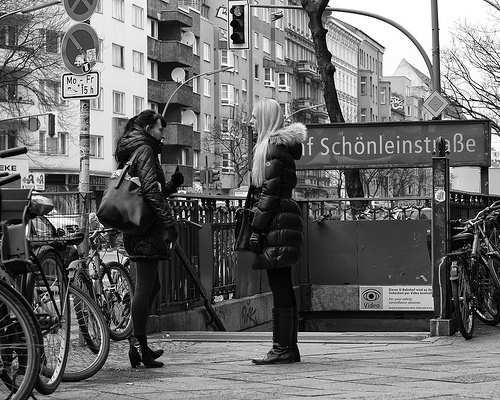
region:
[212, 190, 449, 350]
Entrance to underground subway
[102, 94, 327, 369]
Two women talking on street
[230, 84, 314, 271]
Woman with blond hair and black jacket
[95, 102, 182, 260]
Woman with dark hair and dark jacket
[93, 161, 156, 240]
Purse on woman's shoulder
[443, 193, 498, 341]
Bicycle up against wall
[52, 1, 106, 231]
Street sign in city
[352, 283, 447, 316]
Video recording warning sign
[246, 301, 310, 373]
Black boots woman is wearing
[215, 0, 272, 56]
Traffic signal over street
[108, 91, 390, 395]
two women are talking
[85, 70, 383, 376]
two women standing at the subway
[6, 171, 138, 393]
the bikes are parked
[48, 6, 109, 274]
signs on the pole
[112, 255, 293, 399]
women are wearing boots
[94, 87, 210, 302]
a woman is carrying a shoulder bag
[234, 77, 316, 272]
the woman is blonde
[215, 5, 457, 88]
traffic light attached to a pole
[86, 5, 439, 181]
the buildings beside the street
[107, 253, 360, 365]
the women are wearing leggings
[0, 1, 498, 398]
picture was taken in berlin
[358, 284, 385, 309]
video [eye] warning on subway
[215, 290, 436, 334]
entrance to subway w/ graffiti on left concrete wall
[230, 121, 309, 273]
a puffy jacket w/ a furry hood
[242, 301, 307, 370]
flat mid calf boots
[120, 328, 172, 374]
medium heel ankle boots, dark colour, metallic stripe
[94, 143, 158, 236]
overfull one shoulder tote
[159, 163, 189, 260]
black or dark colour pair of gloves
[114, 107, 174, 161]
a large hood on a jacket worn by a dark haired woman w/ a ponytail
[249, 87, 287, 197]
long straight blonde hair any woman in the late 60s wouldve killed for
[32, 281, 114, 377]
the rubber wheel of the bike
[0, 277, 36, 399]
the rubber wheel of the bike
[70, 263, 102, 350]
the rubber wheel of the bike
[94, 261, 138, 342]
the rubber wheel of the bike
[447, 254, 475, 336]
the rubber wheel of the bike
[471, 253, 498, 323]
the rubber wheel of the bike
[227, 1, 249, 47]
the traffic light above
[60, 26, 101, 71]
the circle sign on the pole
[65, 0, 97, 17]
the circle sign on the pole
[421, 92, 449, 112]
the diamond sign on the pole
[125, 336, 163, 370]
a black leather boot of a woman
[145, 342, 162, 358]
a black leather boot of a woman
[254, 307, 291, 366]
a black leather boot of a woman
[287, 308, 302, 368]
a black leather boot of a woman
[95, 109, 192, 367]
a brunette woman standing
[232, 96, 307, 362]
a blond woman standing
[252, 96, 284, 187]
long blond straight hair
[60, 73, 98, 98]
a black and white sign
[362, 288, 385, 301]
a picture of an eye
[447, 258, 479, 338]
the wheel of a bike